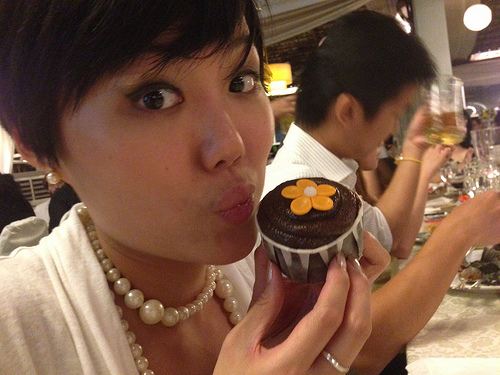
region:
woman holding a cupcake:
[71, 48, 425, 344]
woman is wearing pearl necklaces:
[40, 83, 284, 368]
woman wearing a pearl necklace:
[76, 205, 244, 374]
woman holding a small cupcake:
[256, 170, 363, 278]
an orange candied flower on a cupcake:
[282, 177, 336, 217]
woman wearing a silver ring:
[320, 348, 348, 373]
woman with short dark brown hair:
[3, 1, 273, 265]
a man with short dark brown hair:
[296, 7, 433, 147]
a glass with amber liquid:
[426, 75, 466, 143]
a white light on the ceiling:
[461, 3, 491, 29]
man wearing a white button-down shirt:
[263, 123, 390, 260]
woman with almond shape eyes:
[126, 70, 261, 112]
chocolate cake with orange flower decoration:
[256, 173, 368, 276]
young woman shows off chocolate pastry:
[6, 6, 388, 372]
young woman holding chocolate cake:
[1, 0, 377, 373]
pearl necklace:
[78, 214, 245, 373]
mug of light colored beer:
[431, 78, 466, 145]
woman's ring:
[321, 348, 351, 373]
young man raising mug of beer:
[261, 11, 468, 256]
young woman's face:
[1, 2, 273, 274]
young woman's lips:
[208, 180, 257, 225]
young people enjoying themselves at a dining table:
[6, 5, 497, 373]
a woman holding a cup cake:
[5, 49, 396, 365]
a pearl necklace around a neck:
[91, 237, 255, 372]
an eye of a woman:
[130, 79, 187, 123]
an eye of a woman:
[225, 62, 263, 105]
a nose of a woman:
[192, 99, 251, 176]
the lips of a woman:
[204, 177, 264, 226]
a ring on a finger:
[317, 342, 356, 373]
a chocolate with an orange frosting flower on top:
[249, 162, 374, 289]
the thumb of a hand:
[223, 262, 290, 353]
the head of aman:
[289, 47, 436, 177]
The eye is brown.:
[117, 72, 199, 122]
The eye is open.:
[110, 70, 200, 122]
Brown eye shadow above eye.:
[111, 65, 196, 122]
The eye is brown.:
[221, 60, 268, 109]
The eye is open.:
[216, 57, 265, 106]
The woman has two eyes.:
[2, 0, 298, 295]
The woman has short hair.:
[1, 0, 303, 292]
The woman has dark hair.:
[0, 0, 298, 293]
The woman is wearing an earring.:
[0, 0, 291, 290]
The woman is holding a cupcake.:
[1, 0, 398, 373]